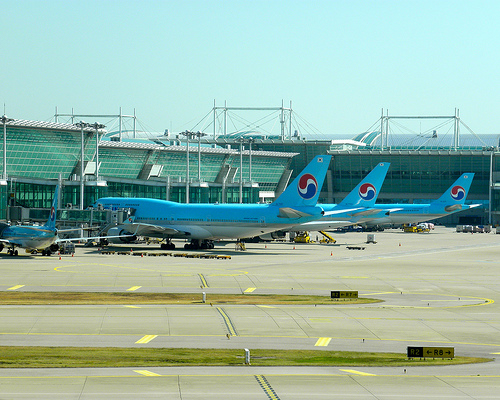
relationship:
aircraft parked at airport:
[83, 153, 485, 250] [8, 88, 497, 258]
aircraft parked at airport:
[314, 172, 488, 230] [8, 88, 497, 258]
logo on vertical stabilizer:
[295, 172, 317, 199] [270, 152, 332, 205]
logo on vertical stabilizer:
[357, 182, 376, 199] [335, 160, 391, 208]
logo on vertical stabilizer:
[449, 184, 465, 200] [430, 171, 476, 203]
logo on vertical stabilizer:
[48, 205, 54, 222] [43, 178, 60, 228]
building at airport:
[0, 117, 495, 224] [0, 122, 492, 392]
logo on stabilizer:
[449, 184, 465, 200] [432, 170, 470, 209]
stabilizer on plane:
[11, 215, 111, 236] [0, 170, 130, 255]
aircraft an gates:
[83, 153, 485, 250] [15, 177, 256, 244]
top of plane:
[102, 192, 269, 212] [95, 157, 370, 236]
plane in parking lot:
[0, 170, 135, 256] [0, 220, 492, 393]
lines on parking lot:
[4, 260, 489, 398] [0, 220, 492, 393]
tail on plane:
[270, 154, 332, 199] [88, 182, 343, 250]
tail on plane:
[438, 170, 475, 200] [88, 182, 343, 250]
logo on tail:
[295, 172, 317, 199] [270, 154, 332, 199]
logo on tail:
[449, 184, 465, 200] [438, 170, 475, 200]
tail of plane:
[270, 154, 332, 199] [91, 147, 376, 261]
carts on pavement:
[453, 220, 492, 234] [0, 225, 497, 398]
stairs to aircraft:
[316, 225, 339, 250] [83, 153, 485, 250]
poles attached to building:
[441, 100, 474, 176] [328, 101, 498, 231]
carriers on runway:
[93, 241, 238, 270] [4, 246, 488, 398]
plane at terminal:
[0, 170, 135, 256] [2, 172, 293, 232]